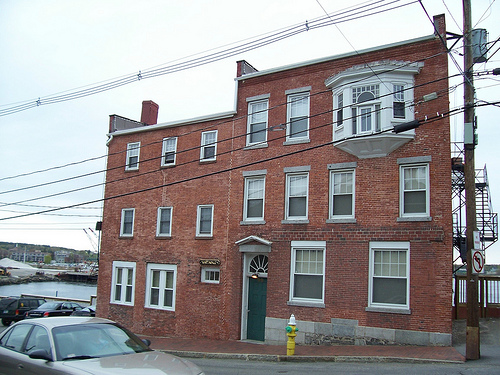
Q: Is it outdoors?
A: Yes, it is outdoors.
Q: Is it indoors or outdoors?
A: It is outdoors.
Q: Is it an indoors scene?
A: No, it is outdoors.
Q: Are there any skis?
A: No, there are no skis.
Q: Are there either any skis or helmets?
A: No, there are no skis or helmets.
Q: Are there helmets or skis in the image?
A: No, there are no skis or helmets.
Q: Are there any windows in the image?
A: Yes, there is a window.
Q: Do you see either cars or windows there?
A: Yes, there is a window.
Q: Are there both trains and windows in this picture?
A: No, there is a window but no trains.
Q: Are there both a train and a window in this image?
A: No, there is a window but no trains.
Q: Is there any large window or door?
A: Yes, there is a large window.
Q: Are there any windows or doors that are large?
A: Yes, the window is large.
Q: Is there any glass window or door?
A: Yes, there is a glass window.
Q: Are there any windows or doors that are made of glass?
A: Yes, the window is made of glass.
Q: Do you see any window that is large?
A: Yes, there is a large window.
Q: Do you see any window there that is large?
A: Yes, there is a window that is large.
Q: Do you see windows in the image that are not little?
A: Yes, there is a large window.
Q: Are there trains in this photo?
A: No, there are no trains.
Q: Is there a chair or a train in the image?
A: No, there are no trains or chairs.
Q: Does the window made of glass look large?
A: Yes, the window is large.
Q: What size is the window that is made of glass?
A: The window is large.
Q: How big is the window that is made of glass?
A: The window is large.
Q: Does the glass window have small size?
A: No, the window is large.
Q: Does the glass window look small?
A: No, the window is large.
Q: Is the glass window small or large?
A: The window is large.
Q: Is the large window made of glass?
A: Yes, the window is made of glass.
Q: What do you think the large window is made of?
A: The window is made of glass.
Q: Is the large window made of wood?
A: No, the window is made of glass.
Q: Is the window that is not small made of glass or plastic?
A: The window is made of glass.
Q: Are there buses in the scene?
A: No, there are no buses.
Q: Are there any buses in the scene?
A: No, there are no buses.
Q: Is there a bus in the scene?
A: No, there are no buses.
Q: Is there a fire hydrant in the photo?
A: Yes, there is a fire hydrant.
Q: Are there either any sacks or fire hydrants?
A: Yes, there is a fire hydrant.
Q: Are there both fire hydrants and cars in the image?
A: Yes, there are both a fire hydrant and a car.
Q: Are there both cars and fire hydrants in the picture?
A: Yes, there are both a fire hydrant and a car.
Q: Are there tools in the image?
A: No, there are no tools.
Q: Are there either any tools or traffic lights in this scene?
A: No, there are no tools or traffic lights.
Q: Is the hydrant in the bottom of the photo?
A: Yes, the hydrant is in the bottom of the image.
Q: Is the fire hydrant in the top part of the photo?
A: No, the fire hydrant is in the bottom of the image.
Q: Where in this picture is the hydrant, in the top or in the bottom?
A: The hydrant is in the bottom of the image.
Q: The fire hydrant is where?
A: The fire hydrant is on the road.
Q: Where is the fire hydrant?
A: The fire hydrant is on the road.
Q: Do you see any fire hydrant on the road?
A: Yes, there is a fire hydrant on the road.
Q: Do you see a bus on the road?
A: No, there is a fire hydrant on the road.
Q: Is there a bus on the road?
A: No, there is a fire hydrant on the road.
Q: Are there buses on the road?
A: No, there is a fire hydrant on the road.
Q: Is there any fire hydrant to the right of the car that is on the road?
A: Yes, there is a fire hydrant to the right of the car.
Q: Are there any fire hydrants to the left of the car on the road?
A: No, the fire hydrant is to the right of the car.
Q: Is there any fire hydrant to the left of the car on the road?
A: No, the fire hydrant is to the right of the car.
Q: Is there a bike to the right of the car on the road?
A: No, there is a fire hydrant to the right of the car.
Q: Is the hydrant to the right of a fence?
A: No, the hydrant is to the right of the car.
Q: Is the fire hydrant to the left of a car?
A: No, the fire hydrant is to the right of a car.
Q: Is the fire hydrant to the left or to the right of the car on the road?
A: The fire hydrant is to the right of the car.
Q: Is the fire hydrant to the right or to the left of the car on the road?
A: The fire hydrant is to the right of the car.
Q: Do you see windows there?
A: Yes, there are windows.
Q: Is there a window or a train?
A: Yes, there are windows.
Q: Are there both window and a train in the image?
A: No, there are windows but no trains.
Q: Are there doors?
A: Yes, there is a door.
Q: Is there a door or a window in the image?
A: Yes, there is a door.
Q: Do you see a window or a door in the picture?
A: Yes, there is a door.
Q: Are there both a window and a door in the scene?
A: Yes, there are both a door and a window.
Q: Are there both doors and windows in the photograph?
A: Yes, there are both a door and a window.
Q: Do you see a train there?
A: No, there are no trains.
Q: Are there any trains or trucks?
A: No, there are no trains or trucks.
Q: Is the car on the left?
A: Yes, the car is on the left of the image.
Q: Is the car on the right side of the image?
A: No, the car is on the left of the image.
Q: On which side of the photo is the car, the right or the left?
A: The car is on the left of the image.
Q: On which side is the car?
A: The car is on the left of the image.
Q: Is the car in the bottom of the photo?
A: Yes, the car is in the bottom of the image.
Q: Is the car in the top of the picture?
A: No, the car is in the bottom of the image.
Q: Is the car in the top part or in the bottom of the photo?
A: The car is in the bottom of the image.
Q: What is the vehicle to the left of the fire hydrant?
A: The vehicle is a car.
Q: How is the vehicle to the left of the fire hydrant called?
A: The vehicle is a car.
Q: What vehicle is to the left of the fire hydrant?
A: The vehicle is a car.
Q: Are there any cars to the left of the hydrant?
A: Yes, there is a car to the left of the hydrant.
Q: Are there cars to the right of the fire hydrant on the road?
A: No, the car is to the left of the fire hydrant.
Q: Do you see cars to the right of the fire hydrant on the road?
A: No, the car is to the left of the fire hydrant.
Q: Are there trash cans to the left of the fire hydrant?
A: No, there is a car to the left of the fire hydrant.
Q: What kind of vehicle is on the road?
A: The vehicle is a car.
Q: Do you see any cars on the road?
A: Yes, there is a car on the road.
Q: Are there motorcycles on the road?
A: No, there is a car on the road.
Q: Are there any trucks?
A: No, there are no trucks.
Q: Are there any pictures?
A: No, there are no pictures.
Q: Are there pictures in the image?
A: No, there are no pictures.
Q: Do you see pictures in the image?
A: No, there are no pictures.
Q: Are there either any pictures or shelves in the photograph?
A: No, there are no pictures or shelves.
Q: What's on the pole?
A: The sign is on the pole.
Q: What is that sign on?
A: The sign is on the pole.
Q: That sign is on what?
A: The sign is on the pole.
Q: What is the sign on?
A: The sign is on the pole.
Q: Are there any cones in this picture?
A: No, there are no cones.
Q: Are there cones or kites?
A: No, there are no cones or kites.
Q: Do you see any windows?
A: Yes, there is a window.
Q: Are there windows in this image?
A: Yes, there is a window.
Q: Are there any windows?
A: Yes, there is a window.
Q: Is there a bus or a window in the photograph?
A: Yes, there is a window.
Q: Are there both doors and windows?
A: Yes, there are both a window and a door.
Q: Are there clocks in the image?
A: No, there are no clocks.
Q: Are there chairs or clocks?
A: No, there are no clocks or chairs.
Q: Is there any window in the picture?
A: Yes, there is a window.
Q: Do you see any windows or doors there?
A: Yes, there is a window.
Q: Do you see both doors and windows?
A: Yes, there are both a window and a door.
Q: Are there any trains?
A: No, there are no trains.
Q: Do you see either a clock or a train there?
A: No, there are no trains or clocks.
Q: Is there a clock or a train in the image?
A: No, there are no trains or clocks.